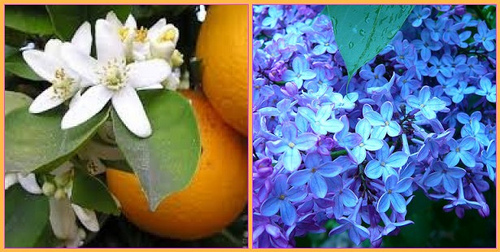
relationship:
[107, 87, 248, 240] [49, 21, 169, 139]
orange under flower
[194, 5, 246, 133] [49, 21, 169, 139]
orange under flower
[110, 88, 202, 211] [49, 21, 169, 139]
leaf under flower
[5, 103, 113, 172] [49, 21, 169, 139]
leaf under flower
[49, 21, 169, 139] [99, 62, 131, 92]
flower has center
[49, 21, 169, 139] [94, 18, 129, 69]
flower has petal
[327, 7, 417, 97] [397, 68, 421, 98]
leaf over flower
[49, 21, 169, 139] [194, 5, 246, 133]
flower by orange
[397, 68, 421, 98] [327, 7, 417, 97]
flower near leaf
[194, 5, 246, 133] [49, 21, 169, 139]
orange by flower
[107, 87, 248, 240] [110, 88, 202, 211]
orange behind leaf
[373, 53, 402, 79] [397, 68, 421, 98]
spot under flower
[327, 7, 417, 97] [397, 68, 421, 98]
leaf above flower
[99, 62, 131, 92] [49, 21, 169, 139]
center of flower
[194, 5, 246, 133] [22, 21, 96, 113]
orange by flower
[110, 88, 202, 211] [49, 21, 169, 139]
leaf touching flower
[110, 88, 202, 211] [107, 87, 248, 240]
leaf touching orange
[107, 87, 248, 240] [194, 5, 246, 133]
orange by orange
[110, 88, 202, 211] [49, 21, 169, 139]
leaf on flower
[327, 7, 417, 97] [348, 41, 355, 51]
leaf has drops